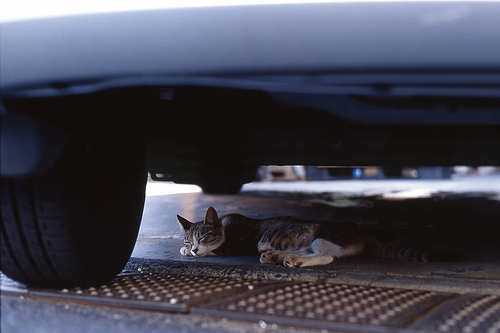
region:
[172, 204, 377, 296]
the cat is sleeping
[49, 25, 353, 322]
a cat under the car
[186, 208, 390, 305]
the car is stripes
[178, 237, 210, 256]
the nose is black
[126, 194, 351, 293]
the cat is stripes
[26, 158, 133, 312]
the tire is black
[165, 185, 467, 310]
the cat is sleeping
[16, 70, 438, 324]
a cat sleeping under a car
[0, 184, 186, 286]
the tire on a car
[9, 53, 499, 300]
the underside of a car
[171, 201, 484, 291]
a cat sleeping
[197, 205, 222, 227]
the ear of a cat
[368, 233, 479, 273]
the tail of a cat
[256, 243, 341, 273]
the feet of a cat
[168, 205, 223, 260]
the head of a cat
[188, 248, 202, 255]
the nose of a cat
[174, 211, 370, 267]
The cat is brown and white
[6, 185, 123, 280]
The tire is black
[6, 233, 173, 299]
Tire sitting on steel grate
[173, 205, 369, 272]
Cat laying under a vehicle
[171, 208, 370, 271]
Cat is sleeping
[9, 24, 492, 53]
The vehicle is white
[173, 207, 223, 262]
Cat with a white beard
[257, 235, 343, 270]
Cat with white legs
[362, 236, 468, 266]
Cat with black tail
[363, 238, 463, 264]
Black and brown stripes on tail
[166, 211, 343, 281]
striped cat under car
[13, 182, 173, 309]
rear tire of car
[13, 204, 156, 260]
tire is black with plenty of tread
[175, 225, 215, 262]
cat has eyes closed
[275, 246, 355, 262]
cat has white paws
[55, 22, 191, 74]
rear bumper of car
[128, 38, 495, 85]
car has blue bumper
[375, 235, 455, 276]
striped tail of cat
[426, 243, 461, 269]
cat's tail has black tip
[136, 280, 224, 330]
metal car is sitting on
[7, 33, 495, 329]
a kitty cat is sleeping under a car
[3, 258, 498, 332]
a metal grate is under the car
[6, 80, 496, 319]
the car is parked on the street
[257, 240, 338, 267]
the cat has white legs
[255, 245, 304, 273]
the pads of the cat's feet are black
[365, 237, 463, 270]
the cat has a striped tail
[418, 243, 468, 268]
the tip of the tail is black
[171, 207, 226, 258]
the cat's eyes are closed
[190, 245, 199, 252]
the cat's nose is pink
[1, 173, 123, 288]
the tires are black and have tread